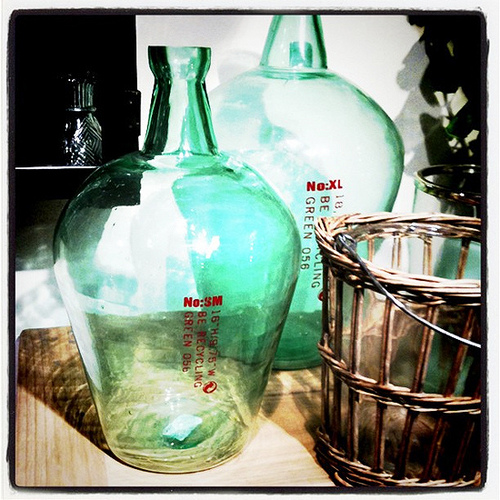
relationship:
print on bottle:
[183, 296, 222, 394] [53, 43, 299, 475]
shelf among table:
[18, 146, 125, 181] [43, 269, 455, 466]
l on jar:
[335, 175, 345, 192] [217, 11, 410, 376]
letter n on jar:
[182, 294, 193, 308] [55, 86, 300, 482]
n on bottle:
[308, 180, 313, 192] [208, 14, 405, 370]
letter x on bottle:
[325, 175, 337, 192] [208, 14, 405, 370]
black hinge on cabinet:
[112, 76, 160, 136] [29, 15, 153, 179]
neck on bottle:
[144, 45, 223, 153] [53, 43, 298, 475]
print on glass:
[183, 296, 222, 394] [75, 41, 312, 488]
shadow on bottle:
[17, 316, 110, 453] [53, 43, 299, 475]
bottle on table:
[53, 43, 299, 475] [22, 409, 97, 479]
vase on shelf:
[63, 61, 105, 163] [16, 157, 107, 189]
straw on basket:
[365, 391, 390, 477] [293, 197, 484, 497]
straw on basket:
[323, 366, 333, 436] [315, 215, 483, 486]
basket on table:
[311, 212, 481, 489] [15, 324, 325, 499]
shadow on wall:
[16, 14, 485, 333] [10, 11, 489, 338]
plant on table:
[412, 14, 487, 160] [17, 271, 89, 486]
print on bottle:
[301, 179, 345, 288] [208, 14, 405, 370]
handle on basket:
[338, 229, 480, 355] [308, 195, 487, 475]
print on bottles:
[175, 294, 229, 399] [106, 15, 369, 462]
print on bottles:
[303, 166, 358, 294] [106, 15, 369, 462]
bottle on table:
[53, 43, 299, 475] [15, 221, 485, 495]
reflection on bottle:
[85, 151, 240, 281] [53, 43, 299, 475]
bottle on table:
[53, 43, 299, 475] [20, 297, 415, 488]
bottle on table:
[208, 14, 405, 370] [23, 288, 134, 415]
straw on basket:
[376, 292, 401, 389] [315, 215, 483, 486]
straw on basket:
[409, 305, 440, 389] [271, 144, 486, 483]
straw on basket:
[370, 402, 388, 471] [300, 204, 495, 497]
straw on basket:
[346, 280, 371, 370] [315, 215, 483, 486]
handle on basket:
[338, 237, 480, 352] [308, 195, 487, 475]